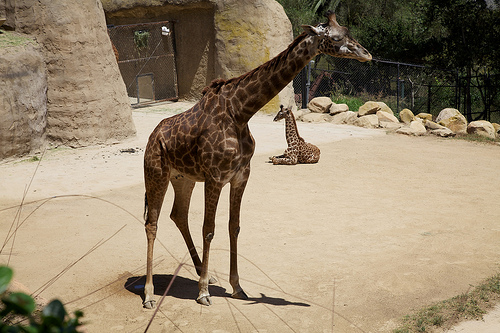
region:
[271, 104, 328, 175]
giraffe sitting on the ground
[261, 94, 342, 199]
giraffe sitting on the ground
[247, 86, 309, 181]
giraffe sitting on the ground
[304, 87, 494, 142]
a pile of stones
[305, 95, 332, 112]
rock is next to rock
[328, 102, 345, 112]
rock is next to rock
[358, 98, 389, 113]
rock is next to rock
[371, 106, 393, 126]
rock is next to rock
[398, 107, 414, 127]
rock is next to rock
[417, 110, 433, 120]
rock is next to rock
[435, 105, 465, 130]
rock is next to rock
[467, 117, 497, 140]
rock is next to rock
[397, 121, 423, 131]
rock is next to rock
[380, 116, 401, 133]
rock is next to rock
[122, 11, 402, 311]
two giraffes in a zoo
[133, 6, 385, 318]
a giraffe standing up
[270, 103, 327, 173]
a giraffe laying down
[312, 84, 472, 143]
a pile of rocks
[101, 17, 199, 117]
a fence in the rock wall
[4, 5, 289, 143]
a rock wall behind the giraffe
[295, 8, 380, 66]
the head of a giraffe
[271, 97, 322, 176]
a baby giraffe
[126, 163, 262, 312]
legs of a giraffe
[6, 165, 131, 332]
plants in the foreground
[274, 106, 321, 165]
a giraffe laying down on the ground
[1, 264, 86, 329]
leaves in the corner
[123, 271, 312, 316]
the shadow of the giraffe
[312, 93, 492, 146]
rocks lined up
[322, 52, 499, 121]
a fence in the background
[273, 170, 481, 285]
the cement on the ground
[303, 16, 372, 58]
the head of the giraffe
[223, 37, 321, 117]
the neck of the giraffe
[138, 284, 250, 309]
the feet of the giraffe